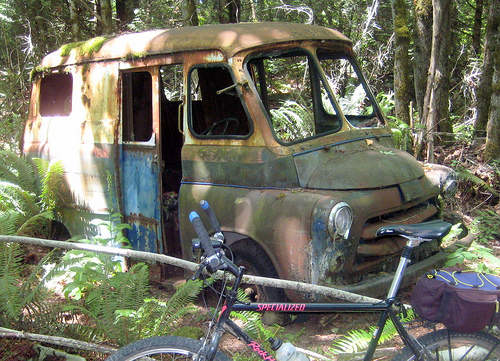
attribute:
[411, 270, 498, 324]
bag — maroon 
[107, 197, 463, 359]
bicycle — pink, gray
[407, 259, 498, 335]
case — dark blue, light blue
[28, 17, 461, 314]
bus — light brown, antique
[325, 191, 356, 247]
headlight — dirty, old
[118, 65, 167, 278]
door — rusted, antique, sliding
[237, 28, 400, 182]
windshield — antique, split, frotn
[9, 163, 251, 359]
forest shrubbery — green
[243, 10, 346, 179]
window — passenger side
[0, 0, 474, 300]
truck — rusted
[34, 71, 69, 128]
window — rear passenger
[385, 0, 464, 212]
tree — brown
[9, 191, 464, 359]
fence — wooden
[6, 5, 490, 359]
scene — during day time, in a forest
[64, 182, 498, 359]
bike — black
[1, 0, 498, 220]
trees — distant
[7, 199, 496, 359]
fence — gray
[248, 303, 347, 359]
bottle — water bottle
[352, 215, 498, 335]
bag — purple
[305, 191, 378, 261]
headlight — clear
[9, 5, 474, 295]
car — old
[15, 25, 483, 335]
car — old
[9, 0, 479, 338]
car — old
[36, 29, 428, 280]
car — old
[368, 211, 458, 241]
seat — black, padded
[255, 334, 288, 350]
lid — black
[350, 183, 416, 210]
area — brown, rusted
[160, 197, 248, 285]
handlebars — black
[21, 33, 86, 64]
moss — green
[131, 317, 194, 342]
tire — black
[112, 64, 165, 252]
door — blue, rusted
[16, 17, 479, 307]
car — old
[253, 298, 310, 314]
writing — pink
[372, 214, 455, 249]
bicycle seat — black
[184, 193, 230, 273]
handles — bicycle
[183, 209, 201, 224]
end — blue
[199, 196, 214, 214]
end — blue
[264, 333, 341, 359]
bottle — water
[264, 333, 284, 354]
top — black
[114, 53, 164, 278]
door — sliding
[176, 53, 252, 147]
window — car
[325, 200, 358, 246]
headlight — broken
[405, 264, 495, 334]
bag — blue, purple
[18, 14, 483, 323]
van — rundown, rusted, old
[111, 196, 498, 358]
mountain bike — black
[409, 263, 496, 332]
cargo bag — dark purple, blue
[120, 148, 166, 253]
paint — blue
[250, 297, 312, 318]
lettering — red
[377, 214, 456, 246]
seat — raised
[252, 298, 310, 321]
paint — pink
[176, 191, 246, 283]
handles — black, blue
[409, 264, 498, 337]
backpack — purple, blue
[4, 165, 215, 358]
plant — green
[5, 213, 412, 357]
gate — wooden